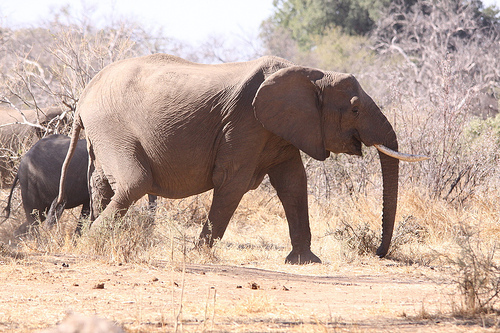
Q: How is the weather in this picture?
A: It is clear.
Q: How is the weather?
A: It is clear.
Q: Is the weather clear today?
A: Yes, it is clear.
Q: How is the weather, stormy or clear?
A: It is clear.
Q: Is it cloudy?
A: No, it is clear.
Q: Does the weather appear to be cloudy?
A: No, it is clear.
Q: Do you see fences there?
A: No, there are no fences.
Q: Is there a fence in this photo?
A: No, there are no fences.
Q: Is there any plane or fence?
A: No, there are no fences or airplanes.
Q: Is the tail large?
A: Yes, the tail is large.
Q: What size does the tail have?
A: The tail has large size.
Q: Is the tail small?
A: No, the tail is large.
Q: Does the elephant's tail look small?
A: No, the tail is large.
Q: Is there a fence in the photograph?
A: No, there are no fences.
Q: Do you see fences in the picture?
A: No, there are no fences.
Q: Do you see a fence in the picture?
A: No, there are no fences.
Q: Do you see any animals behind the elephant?
A: Yes, there is an animal behind the elephant.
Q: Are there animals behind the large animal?
A: Yes, there is an animal behind the elephant.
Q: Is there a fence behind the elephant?
A: No, there is an animal behind the elephant.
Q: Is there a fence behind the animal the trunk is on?
A: No, there is an animal behind the elephant.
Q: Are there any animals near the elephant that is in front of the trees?
A: Yes, there is an animal near the elephant.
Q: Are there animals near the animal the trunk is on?
A: Yes, there is an animal near the elephant.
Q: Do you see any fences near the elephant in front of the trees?
A: No, there is an animal near the elephant.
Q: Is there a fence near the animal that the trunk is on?
A: No, there is an animal near the elephant.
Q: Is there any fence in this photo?
A: No, there are no fences.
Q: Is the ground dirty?
A: Yes, the ground is dirty.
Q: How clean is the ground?
A: The ground is dirty.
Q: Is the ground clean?
A: No, the ground is dirty.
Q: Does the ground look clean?
A: No, the ground is dirty.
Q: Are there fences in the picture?
A: No, there are no fences.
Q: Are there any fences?
A: No, there are no fences.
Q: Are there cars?
A: No, there are no cars.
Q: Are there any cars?
A: No, there are no cars.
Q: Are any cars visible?
A: No, there are no cars.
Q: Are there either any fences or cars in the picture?
A: No, there are no cars or fences.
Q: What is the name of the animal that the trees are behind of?
A: The animal is an elephant.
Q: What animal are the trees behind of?
A: The trees are behind the elephant.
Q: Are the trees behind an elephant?
A: Yes, the trees are behind an elephant.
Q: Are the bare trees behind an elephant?
A: Yes, the trees are behind an elephant.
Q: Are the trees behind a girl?
A: No, the trees are behind an elephant.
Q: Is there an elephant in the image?
A: Yes, there is an elephant.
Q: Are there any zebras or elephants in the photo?
A: Yes, there is an elephant.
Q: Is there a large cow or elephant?
A: Yes, there is a large elephant.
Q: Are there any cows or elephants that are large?
A: Yes, the elephant is large.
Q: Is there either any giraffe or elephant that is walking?
A: Yes, the elephant is walking.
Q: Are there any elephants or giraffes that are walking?
A: Yes, the elephant is walking.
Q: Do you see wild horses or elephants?
A: Yes, there is a wild elephant.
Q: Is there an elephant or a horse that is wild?
A: Yes, the elephant is wild.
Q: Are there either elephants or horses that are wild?
A: Yes, the elephant is wild.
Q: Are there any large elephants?
A: Yes, there is a large elephant.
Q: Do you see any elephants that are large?
A: Yes, there is an elephant that is large.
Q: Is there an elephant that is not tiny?
A: Yes, there is a large elephant.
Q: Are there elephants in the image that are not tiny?
A: Yes, there is a large elephant.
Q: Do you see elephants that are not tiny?
A: Yes, there is a large elephant.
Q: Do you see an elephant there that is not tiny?
A: Yes, there is a large elephant.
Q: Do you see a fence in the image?
A: No, there are no fences.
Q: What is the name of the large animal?
A: The animal is an elephant.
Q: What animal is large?
A: The animal is an elephant.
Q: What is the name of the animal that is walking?
A: The animal is an elephant.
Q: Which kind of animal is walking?
A: The animal is an elephant.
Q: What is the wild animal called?
A: The animal is an elephant.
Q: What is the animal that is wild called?
A: The animal is an elephant.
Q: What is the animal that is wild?
A: The animal is an elephant.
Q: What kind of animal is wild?
A: The animal is an elephant.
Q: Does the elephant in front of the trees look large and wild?
A: Yes, the elephant is large and wild.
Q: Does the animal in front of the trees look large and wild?
A: Yes, the elephant is large and wild.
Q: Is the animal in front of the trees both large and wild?
A: Yes, the elephant is large and wild.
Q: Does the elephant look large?
A: Yes, the elephant is large.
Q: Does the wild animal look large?
A: Yes, the elephant is large.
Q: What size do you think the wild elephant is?
A: The elephant is large.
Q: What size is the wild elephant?
A: The elephant is large.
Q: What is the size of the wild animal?
A: The elephant is large.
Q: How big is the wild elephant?
A: The elephant is large.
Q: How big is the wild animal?
A: The elephant is large.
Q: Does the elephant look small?
A: No, the elephant is large.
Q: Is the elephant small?
A: No, the elephant is large.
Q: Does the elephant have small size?
A: No, the elephant is large.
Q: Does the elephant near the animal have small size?
A: No, the elephant is large.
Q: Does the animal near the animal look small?
A: No, the elephant is large.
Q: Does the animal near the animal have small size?
A: No, the elephant is large.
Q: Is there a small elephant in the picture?
A: No, there is an elephant but it is large.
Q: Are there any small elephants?
A: No, there is an elephant but it is large.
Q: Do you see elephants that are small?
A: No, there is an elephant but it is large.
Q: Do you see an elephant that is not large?
A: No, there is an elephant but it is large.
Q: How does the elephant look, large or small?
A: The elephant is large.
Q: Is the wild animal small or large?
A: The elephant is large.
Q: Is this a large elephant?
A: Yes, this is a large elephant.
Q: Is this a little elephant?
A: No, this is a large elephant.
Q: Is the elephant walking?
A: Yes, the elephant is walking.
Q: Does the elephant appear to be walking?
A: Yes, the elephant is walking.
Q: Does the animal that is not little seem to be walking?
A: Yes, the elephant is walking.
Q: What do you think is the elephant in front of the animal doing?
A: The elephant is walking.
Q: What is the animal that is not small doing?
A: The elephant is walking.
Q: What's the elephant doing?
A: The elephant is walking.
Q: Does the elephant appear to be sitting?
A: No, the elephant is walking.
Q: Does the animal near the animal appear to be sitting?
A: No, the elephant is walking.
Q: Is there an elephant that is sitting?
A: No, there is an elephant but it is walking.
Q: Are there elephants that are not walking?
A: No, there is an elephant but it is walking.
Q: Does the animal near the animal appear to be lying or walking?
A: The elephant is walking.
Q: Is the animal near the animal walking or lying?
A: The elephant is walking.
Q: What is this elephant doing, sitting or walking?
A: The elephant is walking.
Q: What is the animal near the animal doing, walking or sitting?
A: The elephant is walking.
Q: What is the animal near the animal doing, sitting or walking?
A: The elephant is walking.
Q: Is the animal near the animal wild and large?
A: Yes, the elephant is wild and large.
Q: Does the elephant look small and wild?
A: No, the elephant is wild but large.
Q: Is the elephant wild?
A: Yes, the elephant is wild.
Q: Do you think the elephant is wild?
A: Yes, the elephant is wild.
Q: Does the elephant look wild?
A: Yes, the elephant is wild.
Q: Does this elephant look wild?
A: Yes, the elephant is wild.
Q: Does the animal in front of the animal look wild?
A: Yes, the elephant is wild.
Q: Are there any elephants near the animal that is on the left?
A: Yes, there is an elephant near the animal.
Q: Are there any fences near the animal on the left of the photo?
A: No, there is an elephant near the animal.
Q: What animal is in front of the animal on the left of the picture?
A: The elephant is in front of the animal.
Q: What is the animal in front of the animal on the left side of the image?
A: The animal is an elephant.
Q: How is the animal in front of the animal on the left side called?
A: The animal is an elephant.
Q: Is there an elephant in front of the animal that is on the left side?
A: Yes, there is an elephant in front of the animal.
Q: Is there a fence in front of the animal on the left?
A: No, there is an elephant in front of the animal.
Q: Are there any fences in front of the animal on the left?
A: No, there is an elephant in front of the animal.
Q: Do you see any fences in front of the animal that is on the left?
A: No, there is an elephant in front of the animal.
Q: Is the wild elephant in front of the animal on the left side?
A: Yes, the elephant is in front of the animal.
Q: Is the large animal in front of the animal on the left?
A: Yes, the elephant is in front of the animal.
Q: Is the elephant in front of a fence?
A: No, the elephant is in front of the animal.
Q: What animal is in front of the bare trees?
A: The elephant is in front of the trees.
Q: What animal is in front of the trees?
A: The elephant is in front of the trees.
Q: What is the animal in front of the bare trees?
A: The animal is an elephant.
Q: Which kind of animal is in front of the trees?
A: The animal is an elephant.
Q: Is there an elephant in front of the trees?
A: Yes, there is an elephant in front of the trees.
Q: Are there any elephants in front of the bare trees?
A: Yes, there is an elephant in front of the trees.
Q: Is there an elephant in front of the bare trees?
A: Yes, there is an elephant in front of the trees.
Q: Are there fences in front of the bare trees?
A: No, there is an elephant in front of the trees.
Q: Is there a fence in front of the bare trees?
A: No, there is an elephant in front of the trees.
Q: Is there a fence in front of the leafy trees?
A: No, there is an elephant in front of the trees.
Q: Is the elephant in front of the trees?
A: Yes, the elephant is in front of the trees.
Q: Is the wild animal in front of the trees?
A: Yes, the elephant is in front of the trees.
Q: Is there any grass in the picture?
A: Yes, there is grass.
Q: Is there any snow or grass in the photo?
A: Yes, there is grass.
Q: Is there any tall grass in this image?
A: Yes, there is tall grass.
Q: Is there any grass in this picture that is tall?
A: Yes, there is grass that is tall.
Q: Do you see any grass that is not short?
A: Yes, there is tall grass.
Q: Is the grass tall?
A: Yes, the grass is tall.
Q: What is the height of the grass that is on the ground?
A: The grass is tall.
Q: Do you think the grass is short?
A: No, the grass is tall.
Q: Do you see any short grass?
A: No, there is grass but it is tall.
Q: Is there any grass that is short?
A: No, there is grass but it is tall.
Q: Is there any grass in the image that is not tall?
A: No, there is grass but it is tall.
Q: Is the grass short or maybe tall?
A: The grass is tall.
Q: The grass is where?
A: The grass is on the ground.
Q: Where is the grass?
A: The grass is on the ground.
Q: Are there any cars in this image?
A: No, there are no cars.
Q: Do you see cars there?
A: No, there are no cars.